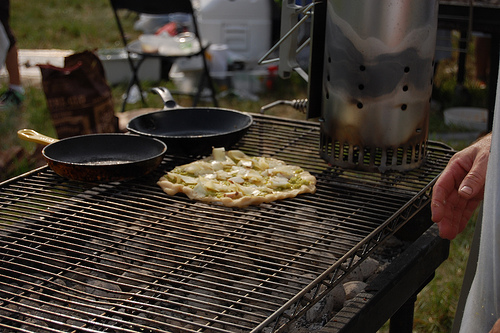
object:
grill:
[0, 92, 467, 333]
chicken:
[213, 147, 226, 159]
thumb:
[457, 153, 490, 201]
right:
[428, 127, 492, 241]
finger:
[431, 160, 460, 222]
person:
[428, 71, 499, 331]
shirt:
[459, 70, 499, 332]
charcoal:
[88, 279, 125, 294]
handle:
[13, 125, 60, 146]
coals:
[347, 252, 381, 271]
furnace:
[311, 2, 441, 171]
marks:
[355, 101, 365, 109]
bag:
[38, 49, 122, 138]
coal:
[24, 319, 51, 333]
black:
[166, 100, 176, 109]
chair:
[104, 3, 222, 110]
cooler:
[177, 2, 283, 73]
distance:
[0, 4, 302, 73]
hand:
[430, 128, 496, 243]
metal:
[279, 116, 314, 123]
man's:
[426, 129, 492, 240]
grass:
[11, 2, 32, 19]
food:
[156, 144, 322, 208]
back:
[11, 2, 130, 48]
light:
[127, 85, 256, 152]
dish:
[16, 128, 168, 185]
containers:
[139, 32, 164, 52]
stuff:
[137, 23, 199, 58]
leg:
[3, 45, 25, 109]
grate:
[0, 94, 447, 333]